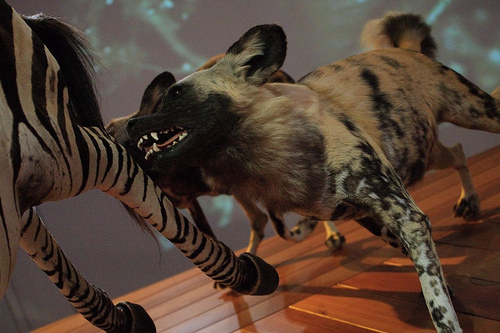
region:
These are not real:
[73, 5, 490, 332]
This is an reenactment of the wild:
[18, 10, 478, 327]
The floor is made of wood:
[143, 237, 419, 322]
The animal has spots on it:
[311, 123, 477, 328]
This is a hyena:
[106, 45, 490, 330]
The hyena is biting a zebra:
[20, 11, 325, 329]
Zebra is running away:
[13, 15, 276, 330]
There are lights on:
[33, 5, 494, 298]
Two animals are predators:
[86, 19, 493, 324]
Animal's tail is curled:
[331, 6, 471, 114]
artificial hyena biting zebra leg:
[14, 5, 493, 325]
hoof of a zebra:
[226, 244, 292, 305]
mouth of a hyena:
[127, 123, 199, 160]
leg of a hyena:
[339, 182, 464, 324]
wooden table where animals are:
[138, 269, 200, 318]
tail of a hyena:
[357, 5, 444, 59]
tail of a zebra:
[30, 2, 113, 128]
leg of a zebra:
[5, 218, 173, 327]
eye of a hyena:
[160, 80, 195, 100]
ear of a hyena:
[227, 20, 292, 81]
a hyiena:
[85, 18, 493, 330]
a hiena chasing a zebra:
[82, 16, 494, 284]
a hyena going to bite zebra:
[87, 18, 492, 315]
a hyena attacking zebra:
[25, 38, 490, 285]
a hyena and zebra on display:
[67, 18, 496, 331]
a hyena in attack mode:
[130, 32, 497, 245]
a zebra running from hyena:
[9, 21, 285, 331]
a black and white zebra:
[4, 15, 268, 332]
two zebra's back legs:
[25, 107, 292, 330]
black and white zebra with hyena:
[22, 17, 472, 242]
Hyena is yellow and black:
[118, 42, 495, 327]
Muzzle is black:
[116, 120, 221, 155]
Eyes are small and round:
[171, 79, 186, 99]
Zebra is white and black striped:
[0, 4, 274, 326]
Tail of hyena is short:
[361, 8, 447, 60]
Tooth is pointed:
[143, 134, 163, 141]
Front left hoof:
[207, 245, 294, 298]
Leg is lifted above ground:
[268, 208, 329, 245]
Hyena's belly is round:
[336, 83, 451, 176]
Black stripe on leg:
[44, 265, 67, 280]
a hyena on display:
[48, 10, 495, 281]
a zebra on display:
[16, 16, 279, 331]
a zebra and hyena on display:
[7, 6, 487, 271]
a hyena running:
[10, 12, 493, 269]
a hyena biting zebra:
[28, 17, 498, 324]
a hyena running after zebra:
[29, 29, 433, 330]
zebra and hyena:
[23, 17, 455, 329]